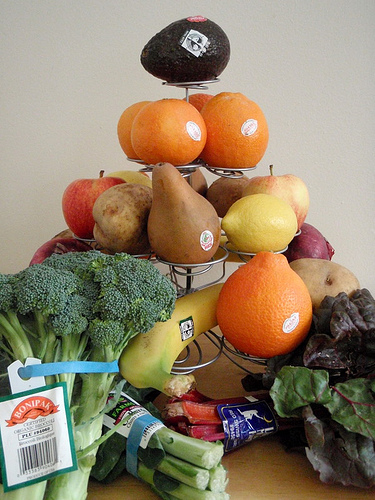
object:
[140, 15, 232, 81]
avocado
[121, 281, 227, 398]
banana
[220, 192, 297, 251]
lemon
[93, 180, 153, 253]
potato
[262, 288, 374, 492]
lettuce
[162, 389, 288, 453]
rhubarb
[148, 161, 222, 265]
pear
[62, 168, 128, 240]
apple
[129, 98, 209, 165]
orange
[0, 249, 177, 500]
broccoli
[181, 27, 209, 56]
sticker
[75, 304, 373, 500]
table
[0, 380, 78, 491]
label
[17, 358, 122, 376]
rubberband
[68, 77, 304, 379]
rack